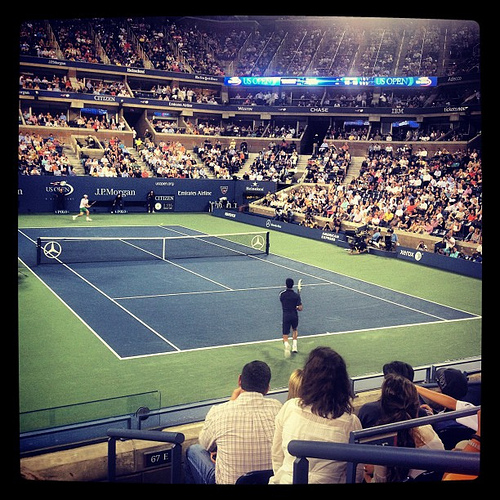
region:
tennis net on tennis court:
[33, 230, 272, 263]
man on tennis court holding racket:
[276, 275, 304, 359]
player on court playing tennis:
[71, 192, 92, 219]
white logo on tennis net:
[42, 237, 64, 259]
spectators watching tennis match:
[189, 345, 358, 487]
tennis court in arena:
[19, 218, 484, 373]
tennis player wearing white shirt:
[73, 193, 94, 223]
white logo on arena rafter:
[308, 103, 333, 115]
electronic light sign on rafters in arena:
[226, 75, 438, 91]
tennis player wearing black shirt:
[278, 273, 301, 357]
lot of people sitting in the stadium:
[333, 141, 455, 234]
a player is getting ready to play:
[276, 276, 310, 361]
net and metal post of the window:
[36, 229, 276, 260]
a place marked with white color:
[69, 223, 265, 356]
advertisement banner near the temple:
[98, 181, 234, 206]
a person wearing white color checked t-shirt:
[207, 384, 273, 484]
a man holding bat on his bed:
[283, 270, 305, 318]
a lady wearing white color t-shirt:
[288, 395, 352, 452]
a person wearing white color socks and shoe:
[278, 334, 305, 359]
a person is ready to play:
[68, 191, 99, 228]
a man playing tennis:
[277, 276, 305, 358]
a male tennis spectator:
[187, 359, 282, 481]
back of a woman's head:
[298, 346, 358, 419]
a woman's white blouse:
[267, 400, 364, 485]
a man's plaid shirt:
[200, 394, 289, 481]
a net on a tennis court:
[37, 233, 274, 263]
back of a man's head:
[239, 359, 273, 393]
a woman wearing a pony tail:
[362, 376, 449, 481]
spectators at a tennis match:
[181, 345, 484, 483]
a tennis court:
[14, 223, 469, 360]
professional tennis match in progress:
[8, 19, 490, 490]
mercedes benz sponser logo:
[38, 236, 63, 263]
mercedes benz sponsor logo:
[248, 232, 264, 252]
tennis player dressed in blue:
[275, 272, 303, 358]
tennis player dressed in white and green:
[71, 192, 87, 220]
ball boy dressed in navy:
[107, 190, 127, 220]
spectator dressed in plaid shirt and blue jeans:
[180, 360, 280, 488]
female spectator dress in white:
[270, 342, 365, 487]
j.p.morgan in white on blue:
[93, 180, 137, 201]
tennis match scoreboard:
[222, 73, 442, 92]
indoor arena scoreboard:
[221, 75, 431, 87]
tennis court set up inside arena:
[20, 213, 482, 357]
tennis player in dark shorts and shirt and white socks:
[275, 276, 305, 359]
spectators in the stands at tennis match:
[177, 345, 482, 481]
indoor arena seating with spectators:
[21, 7, 485, 256]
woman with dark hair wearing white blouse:
[271, 346, 360, 481]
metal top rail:
[285, 439, 482, 469]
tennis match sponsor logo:
[250, 234, 265, 250]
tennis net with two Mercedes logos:
[35, 230, 270, 265]